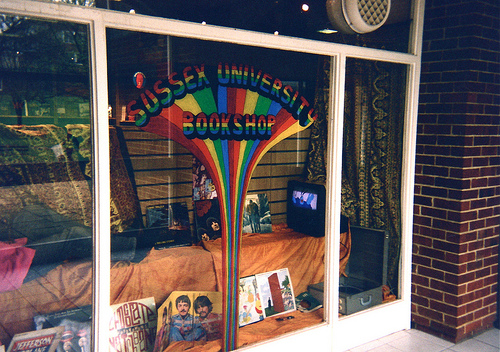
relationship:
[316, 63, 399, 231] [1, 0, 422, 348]
curtains on window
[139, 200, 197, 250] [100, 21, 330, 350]
cover in window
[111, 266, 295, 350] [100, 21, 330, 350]
records in window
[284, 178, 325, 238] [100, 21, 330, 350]
tv in window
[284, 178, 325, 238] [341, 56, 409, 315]
tv in window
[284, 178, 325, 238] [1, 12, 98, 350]
tv in window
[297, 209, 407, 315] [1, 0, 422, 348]
box in window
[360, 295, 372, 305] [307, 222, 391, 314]
handle of box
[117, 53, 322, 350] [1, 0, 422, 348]
design on window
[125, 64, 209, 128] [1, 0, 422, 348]
sussex on window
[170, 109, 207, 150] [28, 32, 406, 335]
b on window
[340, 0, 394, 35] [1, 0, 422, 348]
air vent on window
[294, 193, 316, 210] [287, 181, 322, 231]
screen of tv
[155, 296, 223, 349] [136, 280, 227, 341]
four men on book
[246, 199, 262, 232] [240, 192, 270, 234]
couple on cover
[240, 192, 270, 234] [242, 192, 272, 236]
cover of book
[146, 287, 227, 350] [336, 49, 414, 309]
photo in window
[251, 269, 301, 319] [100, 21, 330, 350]
photo in window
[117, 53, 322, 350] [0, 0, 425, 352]
design on bookstore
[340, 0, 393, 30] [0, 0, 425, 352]
air vent on bookstore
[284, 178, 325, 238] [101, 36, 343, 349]
tv in window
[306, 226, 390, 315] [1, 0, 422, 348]
box in window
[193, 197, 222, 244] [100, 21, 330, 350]
album cover in window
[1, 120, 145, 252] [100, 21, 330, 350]
rug in window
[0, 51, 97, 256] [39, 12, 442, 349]
reflections in window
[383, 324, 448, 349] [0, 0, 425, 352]
concrete tile in front of bookstore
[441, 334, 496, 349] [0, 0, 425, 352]
concrete tile in front of bookstore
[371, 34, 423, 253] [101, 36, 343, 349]
frame in front of window